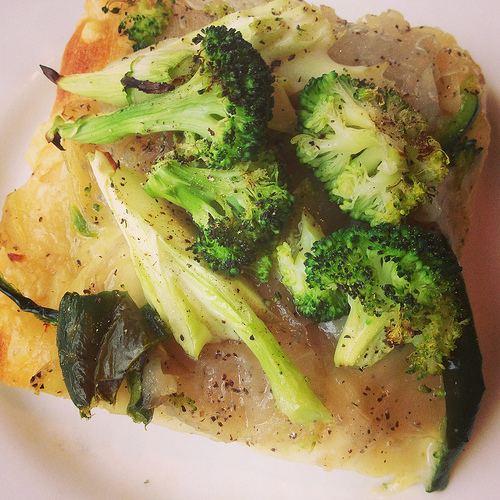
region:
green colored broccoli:
[108, 53, 265, 152]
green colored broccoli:
[148, 160, 300, 268]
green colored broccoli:
[307, 232, 452, 404]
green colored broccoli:
[300, 77, 453, 231]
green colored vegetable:
[50, 280, 177, 418]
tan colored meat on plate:
[33, 181, 148, 277]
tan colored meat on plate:
[187, 365, 250, 432]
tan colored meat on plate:
[338, 20, 458, 56]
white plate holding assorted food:
[20, 416, 210, 496]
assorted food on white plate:
[211, 350, 366, 487]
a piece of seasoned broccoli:
[77, 25, 272, 135]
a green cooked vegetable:
[36, 265, 177, 431]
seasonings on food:
[174, 359, 256, 442]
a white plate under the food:
[17, 424, 177, 481]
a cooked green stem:
[85, 137, 346, 445]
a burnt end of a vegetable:
[33, 56, 74, 101]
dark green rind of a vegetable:
[387, 310, 498, 472]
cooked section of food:
[42, 12, 121, 158]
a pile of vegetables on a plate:
[9, 10, 499, 496]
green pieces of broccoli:
[88, 25, 473, 382]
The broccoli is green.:
[311, 234, 445, 376]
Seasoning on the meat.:
[350, 383, 417, 470]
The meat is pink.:
[216, 364, 381, 458]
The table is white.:
[44, 442, 141, 477]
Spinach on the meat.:
[54, 293, 170, 416]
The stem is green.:
[226, 311, 326, 425]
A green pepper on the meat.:
[411, 245, 487, 474]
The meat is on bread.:
[63, 30, 117, 73]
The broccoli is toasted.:
[361, 100, 428, 164]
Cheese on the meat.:
[15, 223, 55, 273]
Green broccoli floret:
[98, 22, 277, 172]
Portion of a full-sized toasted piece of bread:
[61, 22, 121, 69]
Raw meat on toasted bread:
[196, 361, 445, 456]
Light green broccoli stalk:
[332, 310, 394, 370]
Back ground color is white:
[463, 6, 499, 49]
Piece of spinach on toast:
[88, 183, 186, 284]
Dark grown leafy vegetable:
[58, 294, 148, 411]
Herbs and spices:
[344, 382, 424, 453]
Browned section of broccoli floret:
[363, 97, 438, 157]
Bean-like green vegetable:
[451, 71, 485, 148]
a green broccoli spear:
[50, 29, 270, 166]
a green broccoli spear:
[141, 136, 289, 268]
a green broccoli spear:
[297, 72, 442, 219]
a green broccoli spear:
[302, 217, 448, 367]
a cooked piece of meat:
[0, 2, 482, 492]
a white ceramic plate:
[0, 2, 498, 497]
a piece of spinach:
[42, 276, 174, 423]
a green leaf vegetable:
[73, 141, 318, 431]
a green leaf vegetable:
[55, 4, 385, 130]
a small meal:
[3, 0, 489, 497]